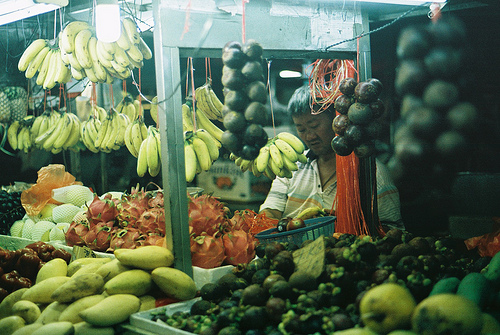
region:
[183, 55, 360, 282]
A man at a fruit stand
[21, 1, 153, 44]
A hanging light bulb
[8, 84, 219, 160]
Hanging banana bunches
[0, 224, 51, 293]
Red, bell peppers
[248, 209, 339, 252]
A bowl with fruit in it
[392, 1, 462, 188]
Hanging fruit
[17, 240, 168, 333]
A bunch of yellow vegetables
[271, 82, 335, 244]
A man wearing a striped shirt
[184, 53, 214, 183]
Bananas hanging from the ceiling by red cord or rope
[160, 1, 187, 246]
A grey pole or post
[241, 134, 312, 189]
bunch of green bananas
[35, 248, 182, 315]
several green mangoes stacked up high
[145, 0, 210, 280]
tall green piece of board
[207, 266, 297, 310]
bunch of green avocados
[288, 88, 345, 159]
man with salt and pepper hair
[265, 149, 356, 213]
man wearing white and yellow shirt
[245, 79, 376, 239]
man standing behind stall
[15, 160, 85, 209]
piece of orange plastic bag on fruit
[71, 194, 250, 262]
strange looking orange fruit with spikes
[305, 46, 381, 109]
orange and white string arranged in a circle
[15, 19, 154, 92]
a set of yellow bananas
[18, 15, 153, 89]
bananas with dark end tips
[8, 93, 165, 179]
a bunch of yellow bananas with spots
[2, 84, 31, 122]
three green pine apples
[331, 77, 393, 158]
a small bunch of blue grapes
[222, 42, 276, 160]
a large bunch of blue grapes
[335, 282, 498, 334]
a bunch of yellow pears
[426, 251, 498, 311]
Three healthy green cucumbers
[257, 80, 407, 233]
a man with white, blue, yellow and orange shirt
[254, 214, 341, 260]
a blue plastic fruit basket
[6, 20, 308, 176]
bunches of yellow bananas hanging.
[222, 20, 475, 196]
round dark green fruit hanging from orange cord.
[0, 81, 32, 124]
three pineapples in the background.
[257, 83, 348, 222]
A man with black & grey hair standing behind fruit.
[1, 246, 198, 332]
Yellow oblong fruit on a fruit stand.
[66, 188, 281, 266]
Red dragon fruit on a fruit stand.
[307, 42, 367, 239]
a bunch of orange cords hanging in a group.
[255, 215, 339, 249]
some fruit in a basket.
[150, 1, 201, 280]
A grey, square, wooden post in the middle of the fruit.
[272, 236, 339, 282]
A card board sign in a pile of fruit.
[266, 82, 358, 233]
An Asian man at a farmer's market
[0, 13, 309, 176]
yellow bananas hanging in a food stand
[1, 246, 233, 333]
Yellow squash on display at a food stand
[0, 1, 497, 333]
A food stand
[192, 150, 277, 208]
A white box used to transport fruit and vegetables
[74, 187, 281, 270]
An orange colored tropical fruit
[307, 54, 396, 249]
Orange string used to hang fruit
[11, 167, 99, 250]
Individually wrapped lemons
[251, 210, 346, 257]
A Blue basket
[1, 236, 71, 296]
Red fruit